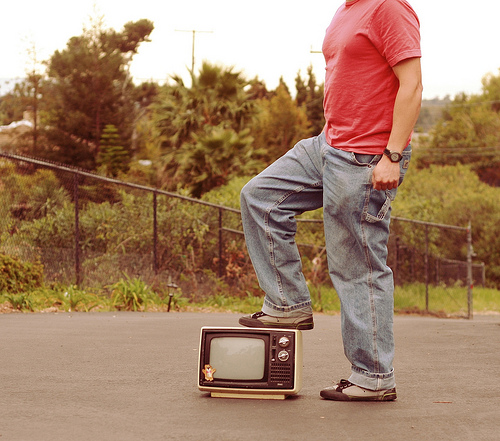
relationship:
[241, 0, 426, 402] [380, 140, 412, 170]
man wearing watch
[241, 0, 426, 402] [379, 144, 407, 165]
man wearing watch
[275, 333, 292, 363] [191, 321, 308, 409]
knobs on television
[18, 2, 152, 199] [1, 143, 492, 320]
pine trees behind fence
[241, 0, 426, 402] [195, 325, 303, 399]
man standing on television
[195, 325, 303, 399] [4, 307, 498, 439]
television on concrete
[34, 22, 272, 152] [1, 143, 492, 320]
trees behind fence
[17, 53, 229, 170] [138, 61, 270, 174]
poles behind trees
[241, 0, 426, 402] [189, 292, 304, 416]
man on tv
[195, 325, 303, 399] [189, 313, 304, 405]
television has screen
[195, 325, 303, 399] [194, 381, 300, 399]
television has white case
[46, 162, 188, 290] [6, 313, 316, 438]
fence next to road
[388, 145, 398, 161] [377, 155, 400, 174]
watch on wrist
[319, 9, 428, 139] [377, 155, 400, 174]
man has wrist